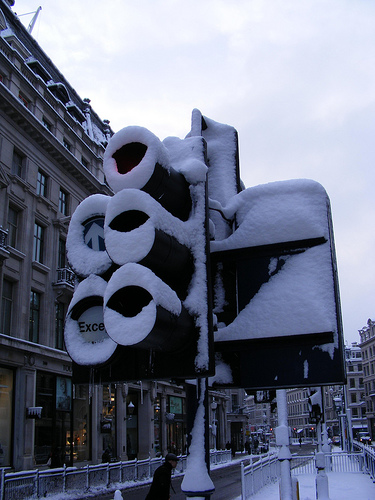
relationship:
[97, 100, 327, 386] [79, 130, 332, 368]
light covered with snow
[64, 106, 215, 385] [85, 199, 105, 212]
signal light covered in snow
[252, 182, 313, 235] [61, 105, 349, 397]
snow on traffic light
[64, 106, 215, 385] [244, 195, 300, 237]
signal light covered in snow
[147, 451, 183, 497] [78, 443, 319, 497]
man crossing th street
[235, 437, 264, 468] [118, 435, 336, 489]
man crossing street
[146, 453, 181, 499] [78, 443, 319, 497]
man crossing street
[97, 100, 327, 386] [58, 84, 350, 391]
light covered with snow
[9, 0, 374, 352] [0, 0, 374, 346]
clouds in blue sky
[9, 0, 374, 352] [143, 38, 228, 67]
clouds in sky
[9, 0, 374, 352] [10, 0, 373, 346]
clouds in sky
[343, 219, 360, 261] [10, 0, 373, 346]
clouds in sky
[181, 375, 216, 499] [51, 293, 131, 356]
pole for sign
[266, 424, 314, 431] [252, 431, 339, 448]
lights along street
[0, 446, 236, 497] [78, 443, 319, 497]
fence down street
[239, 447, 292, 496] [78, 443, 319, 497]
fence down street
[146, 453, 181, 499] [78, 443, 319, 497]
man walking on street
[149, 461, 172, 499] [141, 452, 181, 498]
coat on man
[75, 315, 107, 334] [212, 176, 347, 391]
exce on sign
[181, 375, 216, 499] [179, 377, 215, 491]
pole covered in snow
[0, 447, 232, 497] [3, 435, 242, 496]
fence along sidewalk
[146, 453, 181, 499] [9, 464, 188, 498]
man walking along sidewalk